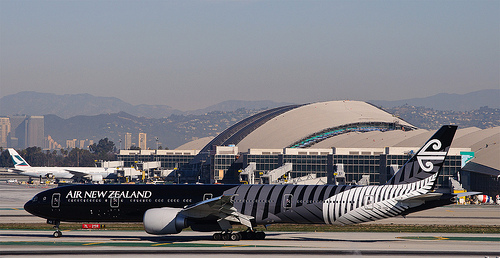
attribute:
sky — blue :
[3, 1, 497, 146]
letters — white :
[64, 192, 152, 198]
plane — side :
[15, 125, 458, 234]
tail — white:
[390, 120, 462, 176]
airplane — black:
[25, 120, 464, 236]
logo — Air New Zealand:
[64, 187, 152, 201]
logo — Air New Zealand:
[60, 189, 153, 202]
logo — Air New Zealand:
[64, 188, 156, 201]